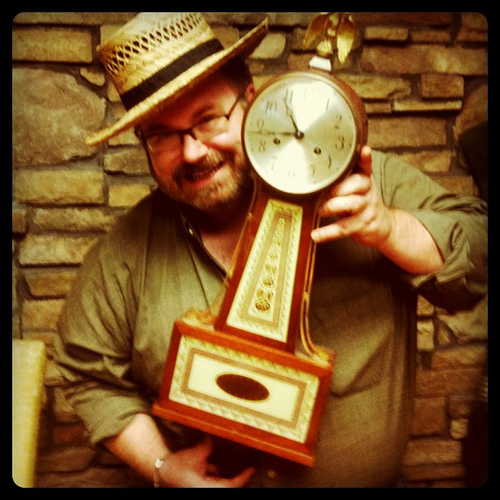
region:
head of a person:
[106, 23, 274, 216]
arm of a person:
[49, 354, 157, 476]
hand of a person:
[168, 426, 263, 490]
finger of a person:
[171, 431, 234, 476]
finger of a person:
[202, 471, 276, 494]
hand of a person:
[320, 149, 398, 265]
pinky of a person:
[290, 219, 365, 267]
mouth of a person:
[179, 145, 243, 202]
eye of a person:
[155, 110, 177, 145]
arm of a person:
[388, 202, 497, 264]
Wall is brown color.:
[29, 25, 442, 335]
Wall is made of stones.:
[26, 30, 422, 415]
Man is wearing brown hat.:
[70, 11, 280, 138]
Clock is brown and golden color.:
[160, 25, 330, 455]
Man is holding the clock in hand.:
[105, 50, 380, 471]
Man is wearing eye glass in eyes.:
[90, 15, 275, 232]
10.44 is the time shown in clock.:
[240, 60, 350, 180]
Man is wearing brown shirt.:
[35, 120, 431, 475]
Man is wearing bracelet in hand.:
[135, 441, 185, 481]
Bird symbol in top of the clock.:
[298, 10, 362, 74]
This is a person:
[53, 13, 498, 485]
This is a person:
[63, 17, 476, 492]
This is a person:
[32, 3, 431, 493]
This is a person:
[63, 8, 495, 498]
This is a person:
[59, 3, 388, 491]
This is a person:
[50, 16, 497, 491]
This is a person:
[29, 5, 463, 489]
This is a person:
[50, 12, 479, 492]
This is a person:
[54, 14, 471, 487]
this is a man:
[47, 19, 416, 485]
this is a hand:
[312, 130, 487, 325]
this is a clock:
[241, 63, 361, 205]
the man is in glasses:
[124, 122, 246, 156]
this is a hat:
[80, 14, 284, 128]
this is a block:
[18, 162, 119, 203]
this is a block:
[347, 60, 412, 108]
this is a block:
[404, 389, 481, 449]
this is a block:
[430, 308, 478, 357]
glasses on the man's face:
[145, 115, 238, 155]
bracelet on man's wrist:
[148, 445, 174, 489]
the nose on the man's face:
[179, 139, 212, 166]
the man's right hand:
[159, 441, 252, 489]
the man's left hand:
[312, 144, 382, 259]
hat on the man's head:
[88, 15, 260, 147]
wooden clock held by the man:
[146, 52, 345, 470]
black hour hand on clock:
[279, 106, 308, 140]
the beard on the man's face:
[172, 153, 243, 210]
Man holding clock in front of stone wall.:
[53, 18, 496, 488]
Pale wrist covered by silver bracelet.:
[147, 446, 174, 490]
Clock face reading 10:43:
[233, 73, 365, 194]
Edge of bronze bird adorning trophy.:
[298, 7, 365, 72]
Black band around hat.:
[104, 30, 231, 109]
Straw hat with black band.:
[56, 11, 279, 151]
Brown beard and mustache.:
[148, 142, 269, 219]